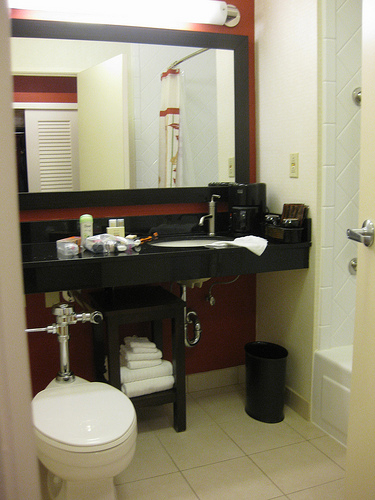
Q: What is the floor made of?
A: Tile.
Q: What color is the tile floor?
A: Beige.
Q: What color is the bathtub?
A: White.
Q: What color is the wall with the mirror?
A: Red.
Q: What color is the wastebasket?
A: Black.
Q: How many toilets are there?
A: One.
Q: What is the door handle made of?
A: Metal.